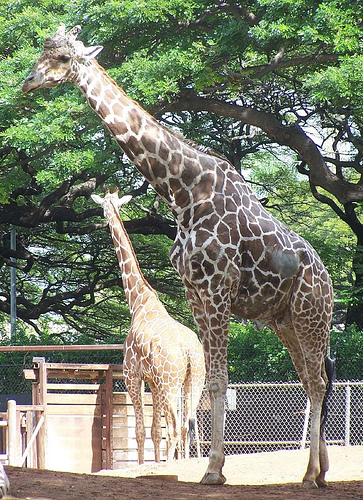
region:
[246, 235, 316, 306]
balding patch on side of giraffe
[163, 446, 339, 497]
giraffe's four feet are in the dirt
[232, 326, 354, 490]
chain link fence around the enclosure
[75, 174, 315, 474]
younger giraffe standing near the older one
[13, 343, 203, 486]
low built wood structure near giraffe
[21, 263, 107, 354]
large branch of tree with leaves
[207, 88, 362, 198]
sky showing through the branches of tree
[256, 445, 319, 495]
shadow cast on the dirt ground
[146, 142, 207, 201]
brown spots in the beige fur of the giraffe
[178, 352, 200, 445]
tail of the small giraffe with hair on the bottom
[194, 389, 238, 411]
white sticker on fence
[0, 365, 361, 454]
chain link fence behind dirt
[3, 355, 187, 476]
wooden structure behind dirt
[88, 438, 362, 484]
sunlight reflected on dirt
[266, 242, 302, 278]
gray spot on brown and white giraffe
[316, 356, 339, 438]
black hair on giraffe tail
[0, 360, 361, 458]
silver rails on chain link fence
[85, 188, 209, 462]
sunlight reflecting on back giraffe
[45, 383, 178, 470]
wooden horizontal slats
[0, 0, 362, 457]
lush green trees behind fence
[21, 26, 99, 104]
the head of a giraffe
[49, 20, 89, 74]
the eye of a giraffe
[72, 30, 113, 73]
the ear of a giraffe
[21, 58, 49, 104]
the nose of a giraffe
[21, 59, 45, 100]
the mouth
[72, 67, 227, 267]
the neck of a giraffe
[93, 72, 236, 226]
the main of a giraffe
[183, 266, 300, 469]
the legs of a giraffe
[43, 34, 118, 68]
the ear of a giraffe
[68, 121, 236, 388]
a brown spotted giraffe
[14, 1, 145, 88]
the head of a giraffe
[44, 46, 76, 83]
the eye of a giraffe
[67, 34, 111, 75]
a ear of a giraffe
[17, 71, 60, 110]
the mouth of a giraffe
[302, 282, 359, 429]
the tail of a giraffe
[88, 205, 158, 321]
the main of a giraffe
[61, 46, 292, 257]
a giraffe near a tree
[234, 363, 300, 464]
short chain link fence around giraffe habitat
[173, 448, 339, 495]
feet of giraffe in the dirt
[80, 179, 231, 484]
small giraffe standing near older giraffe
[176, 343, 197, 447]
long tail on the baby giraffe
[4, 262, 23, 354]
silver metal pole behind fence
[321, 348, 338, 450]
long dark hair on giraffe tail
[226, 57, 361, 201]
sky showing through leafy tree branches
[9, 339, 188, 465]
short wooden fence near small giraffe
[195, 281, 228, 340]
beige fur on giraffe with brown spots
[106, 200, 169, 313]
brown mane on long neck of giraffe